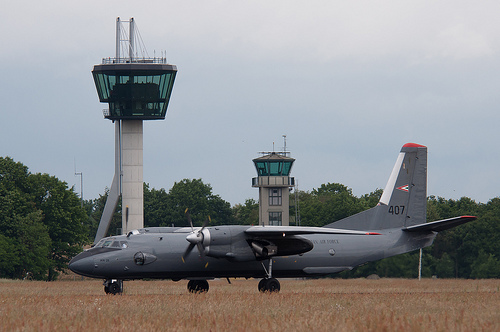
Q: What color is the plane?
A: Silver.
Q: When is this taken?
A: During the day.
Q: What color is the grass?
A: Brown.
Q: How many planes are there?
A: One.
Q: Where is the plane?
A: Parked.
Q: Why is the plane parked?
A: It isn't flying.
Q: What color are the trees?
A: Green.